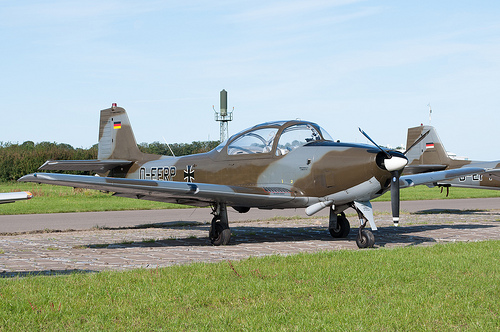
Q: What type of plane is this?
A: A propeller plane.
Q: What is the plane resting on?
A: The wheels.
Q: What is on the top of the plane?
A: The cockpick.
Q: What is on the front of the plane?
A: The propellers.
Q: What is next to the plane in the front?
A: A plane like it.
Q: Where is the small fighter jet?
A: On the runway.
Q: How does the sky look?
A: Bright and blue.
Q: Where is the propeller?
A: On the airplane.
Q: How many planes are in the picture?
A: Two.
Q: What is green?
A: Grass.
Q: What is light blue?
A: The sky.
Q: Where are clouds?
A: In the sky.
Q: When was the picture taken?
A: Daytime.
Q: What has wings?
A: The planes.